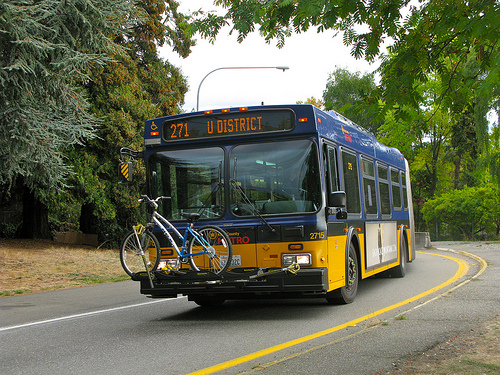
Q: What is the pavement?
A: Gray.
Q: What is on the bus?
A: The bike.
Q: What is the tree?
A: Green and tall.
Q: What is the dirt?
A: Bru.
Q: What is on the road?
A: Lines.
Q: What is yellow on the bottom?
A: The bus.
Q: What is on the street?
A: The bus.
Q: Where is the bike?
A: On the bus.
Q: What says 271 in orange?
A: The bus.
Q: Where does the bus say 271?
A: On the sign.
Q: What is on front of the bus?
A: The bike.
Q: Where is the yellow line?
A: On the street.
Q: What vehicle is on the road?
A: Bus.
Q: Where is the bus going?
A: U district.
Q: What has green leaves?
A: The trees.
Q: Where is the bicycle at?
A: Front of bus.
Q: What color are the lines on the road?
A: Yellow & white.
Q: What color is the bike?
A: Blue.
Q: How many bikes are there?
A: 1.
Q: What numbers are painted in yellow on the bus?
A: 2715.